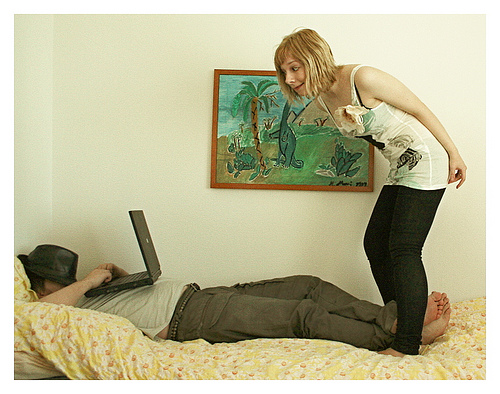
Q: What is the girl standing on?
A: The bed.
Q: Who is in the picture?
A: 2 people.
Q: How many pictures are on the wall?
A: 1.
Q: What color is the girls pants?
A: Black.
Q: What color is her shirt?
A: White.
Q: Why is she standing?
A: To talk to the man.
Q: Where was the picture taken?
A: In a bedroom.